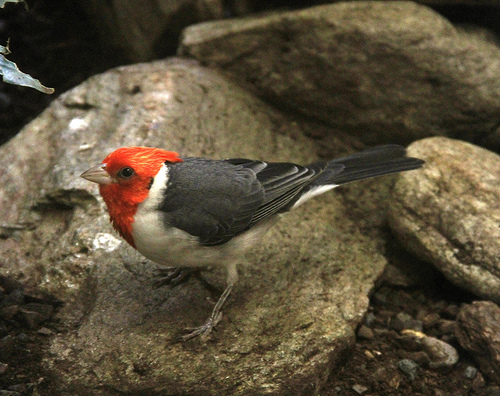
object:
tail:
[308, 146, 427, 189]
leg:
[206, 281, 231, 325]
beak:
[79, 160, 116, 186]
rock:
[175, 0, 500, 148]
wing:
[160, 157, 320, 247]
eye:
[115, 164, 138, 181]